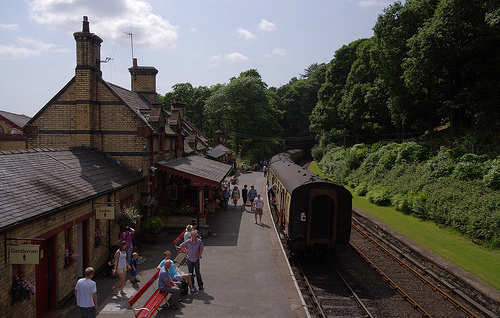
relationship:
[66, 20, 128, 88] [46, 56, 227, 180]
chimney on top of building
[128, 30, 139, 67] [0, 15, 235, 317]
flagpole on top of building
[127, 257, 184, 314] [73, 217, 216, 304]
bench sitting on platform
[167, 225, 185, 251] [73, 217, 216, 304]
bench sitting on platform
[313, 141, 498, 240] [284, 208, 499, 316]
bushes line next to tracks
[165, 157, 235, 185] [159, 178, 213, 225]
covering hanging above platform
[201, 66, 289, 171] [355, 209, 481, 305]
tree next to track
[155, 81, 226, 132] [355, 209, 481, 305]
tree next to track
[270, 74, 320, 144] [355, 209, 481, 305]
tree next to track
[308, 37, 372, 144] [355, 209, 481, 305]
tree next to track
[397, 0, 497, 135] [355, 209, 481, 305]
tree next to track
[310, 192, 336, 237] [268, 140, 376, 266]
door on back of train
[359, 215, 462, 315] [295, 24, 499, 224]
tracks next to trees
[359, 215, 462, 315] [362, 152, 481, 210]
tracks next to bushes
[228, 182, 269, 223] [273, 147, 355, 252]
people waiting for train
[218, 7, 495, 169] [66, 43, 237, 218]
trees next to building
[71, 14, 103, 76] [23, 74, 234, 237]
tower on top of building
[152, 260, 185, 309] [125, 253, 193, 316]
person sitting on bench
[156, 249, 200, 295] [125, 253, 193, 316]
person sitting on bench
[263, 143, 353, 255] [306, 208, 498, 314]
train riding on tracks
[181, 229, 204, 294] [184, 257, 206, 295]
man wearing blue jeans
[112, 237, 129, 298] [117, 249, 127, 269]
woman wearing tank top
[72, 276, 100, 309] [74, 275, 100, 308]
man wearing white shirt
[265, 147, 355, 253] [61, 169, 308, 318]
train at platform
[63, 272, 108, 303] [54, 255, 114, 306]
white shirt of man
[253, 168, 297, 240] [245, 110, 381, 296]
right side of train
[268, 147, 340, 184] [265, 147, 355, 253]
top of train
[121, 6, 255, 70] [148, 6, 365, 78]
clouds in sky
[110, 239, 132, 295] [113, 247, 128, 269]
woman wearing tank top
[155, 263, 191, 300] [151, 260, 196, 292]
man wearing top